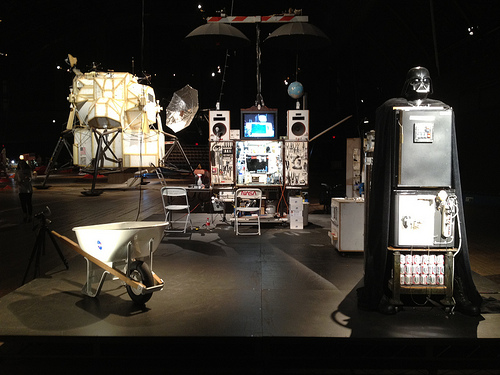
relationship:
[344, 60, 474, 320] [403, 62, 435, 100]
robot made with mask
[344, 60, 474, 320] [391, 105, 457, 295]
robot made with boxes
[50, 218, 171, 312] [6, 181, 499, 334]
wheelbarrow on floor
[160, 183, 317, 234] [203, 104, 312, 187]
table with boxes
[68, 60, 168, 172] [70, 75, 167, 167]
structure composed of panels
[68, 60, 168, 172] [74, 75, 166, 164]
structure composed of strips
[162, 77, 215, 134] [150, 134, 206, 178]
umbrella on stand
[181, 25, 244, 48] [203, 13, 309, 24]
umbrella hanging from bar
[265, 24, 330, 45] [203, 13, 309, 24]
umbrella hanging from bar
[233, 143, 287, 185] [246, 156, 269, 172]
box with opening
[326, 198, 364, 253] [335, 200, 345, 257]
cabinet trimmed in wood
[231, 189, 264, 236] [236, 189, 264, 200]
chair with graffiti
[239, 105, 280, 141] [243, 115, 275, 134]
television has screen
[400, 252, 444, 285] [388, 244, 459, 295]
cans in compartment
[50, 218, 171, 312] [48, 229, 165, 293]
wheelbarrow with handles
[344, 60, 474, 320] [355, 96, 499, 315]
robot wearing cape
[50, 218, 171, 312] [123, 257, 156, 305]
wheelbarrow with tire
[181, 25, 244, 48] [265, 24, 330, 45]
umbrella by umbrella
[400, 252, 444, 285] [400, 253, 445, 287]
cans in stack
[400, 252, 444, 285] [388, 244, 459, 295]
cans in box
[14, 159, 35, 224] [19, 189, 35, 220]
lady in pants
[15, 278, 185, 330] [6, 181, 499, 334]
shadow on floor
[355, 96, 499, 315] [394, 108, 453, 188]
cape over box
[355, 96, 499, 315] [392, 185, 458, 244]
cape over box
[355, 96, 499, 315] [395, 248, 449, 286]
cape over box